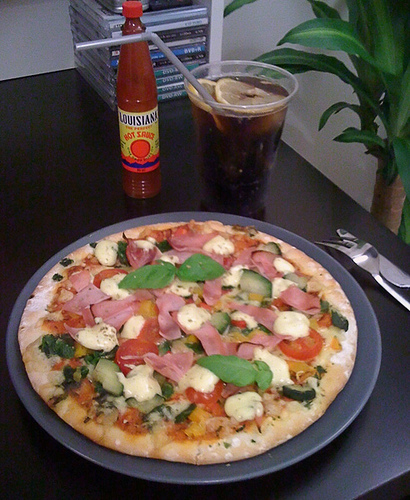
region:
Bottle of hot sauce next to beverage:
[114, 0, 163, 200]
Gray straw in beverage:
[70, 30, 226, 117]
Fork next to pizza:
[311, 232, 408, 318]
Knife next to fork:
[336, 225, 409, 297]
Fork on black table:
[319, 228, 408, 325]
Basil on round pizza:
[190, 348, 272, 389]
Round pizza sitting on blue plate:
[23, 221, 358, 463]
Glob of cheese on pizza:
[106, 363, 162, 405]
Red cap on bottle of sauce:
[121, 2, 141, 16]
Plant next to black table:
[215, 0, 407, 248]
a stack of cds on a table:
[80, 0, 213, 109]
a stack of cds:
[56, 0, 230, 128]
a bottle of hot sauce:
[92, 8, 198, 205]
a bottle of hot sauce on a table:
[97, 11, 188, 253]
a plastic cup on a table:
[140, 51, 296, 221]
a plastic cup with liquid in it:
[141, 42, 313, 240]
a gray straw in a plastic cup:
[59, 15, 334, 218]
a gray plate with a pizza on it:
[33, 212, 380, 490]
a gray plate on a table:
[31, 217, 394, 465]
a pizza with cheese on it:
[33, 230, 334, 474]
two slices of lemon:
[176, 68, 290, 129]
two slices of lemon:
[187, 76, 258, 112]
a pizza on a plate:
[56, 168, 372, 441]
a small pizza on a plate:
[40, 193, 339, 495]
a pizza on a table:
[50, 206, 375, 495]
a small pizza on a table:
[76, 199, 343, 432]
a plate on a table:
[53, 205, 340, 486]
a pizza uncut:
[62, 186, 340, 498]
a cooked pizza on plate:
[56, 191, 405, 481]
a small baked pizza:
[46, 184, 392, 496]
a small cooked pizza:
[51, 231, 346, 457]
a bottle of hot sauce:
[41, 200, 363, 484]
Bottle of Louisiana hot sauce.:
[116, 0, 161, 196]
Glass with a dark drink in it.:
[183, 59, 298, 213]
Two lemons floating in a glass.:
[188, 77, 286, 113]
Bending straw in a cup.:
[74, 31, 223, 114]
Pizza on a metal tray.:
[7, 212, 382, 484]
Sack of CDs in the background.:
[68, 0, 208, 112]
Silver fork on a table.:
[315, 236, 408, 310]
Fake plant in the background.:
[223, 0, 409, 247]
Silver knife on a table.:
[337, 226, 409, 286]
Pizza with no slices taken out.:
[17, 221, 356, 464]